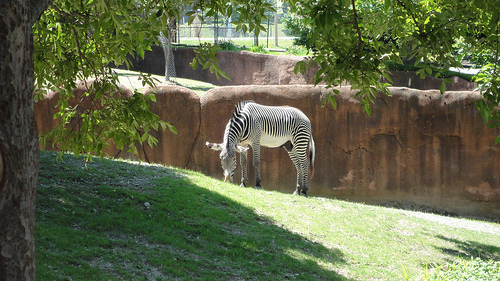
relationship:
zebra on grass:
[223, 96, 313, 167] [134, 199, 309, 262]